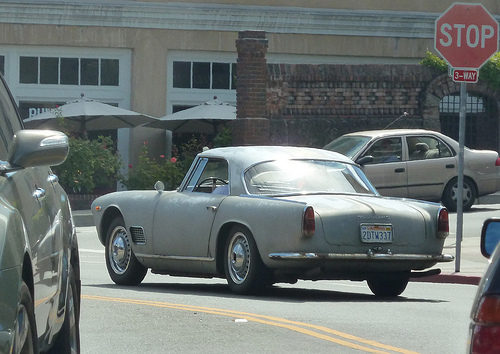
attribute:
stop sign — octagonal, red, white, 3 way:
[431, 1, 499, 70]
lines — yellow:
[79, 292, 417, 354]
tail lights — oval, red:
[299, 204, 449, 239]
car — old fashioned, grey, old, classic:
[90, 143, 454, 296]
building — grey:
[1, 0, 499, 192]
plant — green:
[118, 137, 183, 191]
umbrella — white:
[144, 96, 235, 138]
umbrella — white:
[19, 93, 155, 141]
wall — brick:
[235, 28, 498, 154]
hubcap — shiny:
[229, 235, 251, 278]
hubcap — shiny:
[111, 227, 131, 269]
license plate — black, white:
[358, 222, 393, 244]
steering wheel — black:
[195, 174, 228, 193]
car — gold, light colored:
[322, 127, 499, 211]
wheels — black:
[103, 217, 409, 295]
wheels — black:
[19, 264, 84, 353]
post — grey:
[453, 80, 465, 274]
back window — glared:
[240, 157, 379, 195]